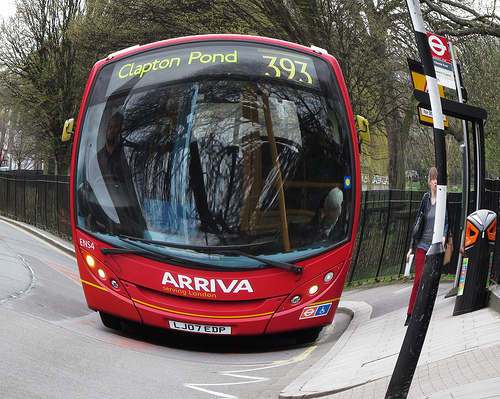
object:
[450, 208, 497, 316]
trash can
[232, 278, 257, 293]
letter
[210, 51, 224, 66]
letter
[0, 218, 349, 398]
asphalt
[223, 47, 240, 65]
letter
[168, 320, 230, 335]
license plate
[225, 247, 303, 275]
windshield wiper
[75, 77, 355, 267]
windshield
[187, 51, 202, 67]
letter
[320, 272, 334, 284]
head light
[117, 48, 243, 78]
destination name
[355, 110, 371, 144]
mirror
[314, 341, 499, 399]
concrete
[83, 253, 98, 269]
head lights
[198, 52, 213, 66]
letter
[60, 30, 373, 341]
bus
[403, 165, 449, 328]
woman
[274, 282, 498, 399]
sidewalk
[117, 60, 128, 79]
letter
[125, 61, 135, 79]
letter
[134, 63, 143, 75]
letter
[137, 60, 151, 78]
letter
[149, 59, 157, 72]
letter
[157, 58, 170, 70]
letter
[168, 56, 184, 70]
letter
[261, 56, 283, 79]
number